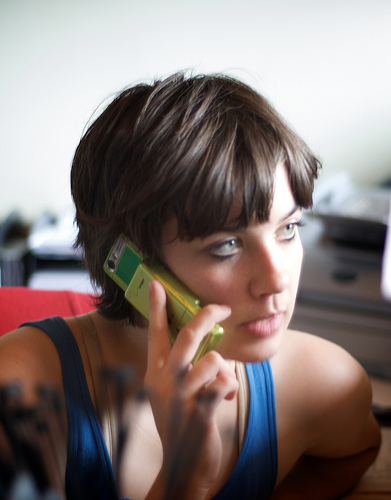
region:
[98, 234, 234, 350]
small green phone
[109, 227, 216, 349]
phone held to ear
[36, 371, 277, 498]
blue top on female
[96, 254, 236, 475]
phone held in right hand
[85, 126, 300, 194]
girl has brown hair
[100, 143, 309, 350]
girl looking to her left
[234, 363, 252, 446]
light brown strap inside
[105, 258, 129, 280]
camera on the phone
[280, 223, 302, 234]
eyes are hazel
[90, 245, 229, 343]
green cellphone in woman's hand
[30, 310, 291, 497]
blue tank top on girl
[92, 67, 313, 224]
straight black hair on woman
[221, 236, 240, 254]
green eye of girl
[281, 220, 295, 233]
green eye of girl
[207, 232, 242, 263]
black eyeliner on girl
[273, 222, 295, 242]
black eyeliner on girl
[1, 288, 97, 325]
red chair behind girl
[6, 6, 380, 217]
white wall behind girl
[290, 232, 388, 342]
brown table behind girl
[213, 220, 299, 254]
girl has green eyes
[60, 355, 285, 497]
girl has blue shirt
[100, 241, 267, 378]
girl has green phone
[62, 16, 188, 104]
white wall behind girl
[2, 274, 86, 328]
red chair behind girl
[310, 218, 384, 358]
grey chest behind girl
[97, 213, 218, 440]
girl holds phone in right hand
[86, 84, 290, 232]
girl has straight hair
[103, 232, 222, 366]
the green phone to the woman's ear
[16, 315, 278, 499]
the blue tank top on the woman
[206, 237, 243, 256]
the right eye on the woman's face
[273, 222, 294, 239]
the left eye on the woman's face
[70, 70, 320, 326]
the woman's short hair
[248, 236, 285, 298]
the nose on the woman's face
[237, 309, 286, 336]
the mouth on the woman's face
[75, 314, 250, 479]
the woman's bra straps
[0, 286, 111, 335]
the red behind the woman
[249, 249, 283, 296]
nose of the woman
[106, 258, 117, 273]
camera of the mobile phone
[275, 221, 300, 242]
eye of the woman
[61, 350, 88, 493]
woman wearing blue color top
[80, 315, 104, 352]
brown strap passing over woman shoulder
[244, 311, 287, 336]
lips of the woman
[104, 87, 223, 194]
hair of the woman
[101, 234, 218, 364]
a green colored cellphone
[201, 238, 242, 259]
the woman's right eye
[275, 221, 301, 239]
the woman's left eye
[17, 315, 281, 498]
a blue tank top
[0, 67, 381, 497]
a woman with brown hair wearing a blue tank top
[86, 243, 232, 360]
a woman holding a phone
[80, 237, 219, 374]
a phone is green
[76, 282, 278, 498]
a woman wearing a shirt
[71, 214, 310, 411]
a woman talking on the phone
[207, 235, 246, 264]
an eye on the woman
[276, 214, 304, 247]
an eye on the woman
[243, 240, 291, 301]
a nose on the woman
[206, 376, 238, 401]
a finger on the hand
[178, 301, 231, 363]
a finger on the hand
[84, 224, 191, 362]
a woman on the phone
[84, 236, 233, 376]
a cell phone is green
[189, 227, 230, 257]
an ey on the woman